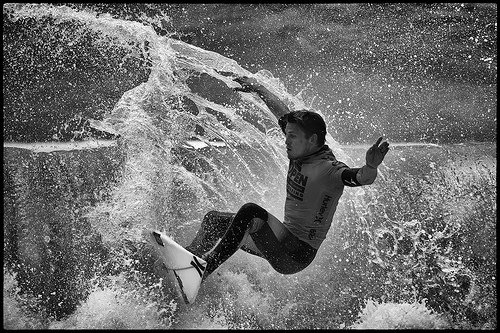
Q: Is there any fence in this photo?
A: No, there are no fences.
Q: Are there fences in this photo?
A: No, there are no fences.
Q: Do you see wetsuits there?
A: Yes, there is a wetsuit.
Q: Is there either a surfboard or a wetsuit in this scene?
A: Yes, there is a wetsuit.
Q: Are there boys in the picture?
A: No, there are no boys.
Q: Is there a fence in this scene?
A: No, there are no fences.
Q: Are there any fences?
A: No, there are no fences.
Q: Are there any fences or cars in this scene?
A: No, there are no fences or cars.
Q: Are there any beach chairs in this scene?
A: No, there are no beach chairs.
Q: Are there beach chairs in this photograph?
A: No, there are no beach chairs.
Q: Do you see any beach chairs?
A: No, there are no beach chairs.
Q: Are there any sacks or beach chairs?
A: No, there are no beach chairs or sacks.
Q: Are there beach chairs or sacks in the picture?
A: No, there are no beach chairs or sacks.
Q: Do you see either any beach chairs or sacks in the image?
A: No, there are no beach chairs or sacks.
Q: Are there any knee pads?
A: No, there are no knee pads.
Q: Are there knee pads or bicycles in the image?
A: No, there are no knee pads or bicycles.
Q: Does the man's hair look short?
A: Yes, the hair is short.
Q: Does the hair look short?
A: Yes, the hair is short.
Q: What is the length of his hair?
A: The hair is short.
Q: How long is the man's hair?
A: The hair is short.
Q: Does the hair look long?
A: No, the hair is short.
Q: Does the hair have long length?
A: No, the hair is short.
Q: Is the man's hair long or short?
A: The hair is short.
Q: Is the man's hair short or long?
A: The hair is short.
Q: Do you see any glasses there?
A: No, there are no glasses.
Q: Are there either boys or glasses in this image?
A: No, there are no glasses or boys.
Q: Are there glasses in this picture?
A: No, there are no glasses.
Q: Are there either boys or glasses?
A: No, there are no glasses or boys.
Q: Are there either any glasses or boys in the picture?
A: No, there are no glasses or boys.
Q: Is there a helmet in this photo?
A: No, there are no helmets.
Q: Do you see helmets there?
A: No, there are no helmets.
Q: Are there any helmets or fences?
A: No, there are no helmets or fences.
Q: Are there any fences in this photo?
A: No, there are no fences.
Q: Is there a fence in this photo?
A: No, there are no fences.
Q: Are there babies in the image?
A: No, there are no babies.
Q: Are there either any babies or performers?
A: No, there are no babies or performers.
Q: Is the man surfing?
A: Yes, the man is surfing.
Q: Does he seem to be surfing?
A: Yes, the man is surfing.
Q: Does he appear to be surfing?
A: Yes, the man is surfing.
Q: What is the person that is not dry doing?
A: The man is surfing.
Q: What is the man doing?
A: The man is surfing.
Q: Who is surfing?
A: The man is surfing.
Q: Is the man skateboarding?
A: No, the man is surfing.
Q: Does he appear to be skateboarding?
A: No, the man is surfing.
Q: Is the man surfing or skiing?
A: The man is surfing.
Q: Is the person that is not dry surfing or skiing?
A: The man is surfing.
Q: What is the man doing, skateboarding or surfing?
A: The man is surfing.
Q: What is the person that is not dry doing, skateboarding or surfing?
A: The man is surfing.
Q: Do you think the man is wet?
A: Yes, the man is wet.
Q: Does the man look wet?
A: Yes, the man is wet.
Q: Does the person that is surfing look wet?
A: Yes, the man is wet.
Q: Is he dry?
A: No, the man is wet.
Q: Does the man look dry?
A: No, the man is wet.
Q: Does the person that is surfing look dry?
A: No, the man is wet.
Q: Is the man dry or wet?
A: The man is wet.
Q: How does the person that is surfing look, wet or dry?
A: The man is wet.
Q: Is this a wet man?
A: Yes, this is a wet man.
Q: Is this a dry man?
A: No, this is a wet man.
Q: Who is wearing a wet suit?
A: The man is wearing a wet suit.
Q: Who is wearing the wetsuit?
A: The man is wearing a wet suit.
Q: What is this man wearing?
A: The man is wearing a wetsuit.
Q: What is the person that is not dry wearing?
A: The man is wearing a wetsuit.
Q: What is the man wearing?
A: The man is wearing a wetsuit.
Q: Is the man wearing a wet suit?
A: Yes, the man is wearing a wet suit.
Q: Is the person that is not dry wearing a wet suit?
A: Yes, the man is wearing a wet suit.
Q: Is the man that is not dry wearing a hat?
A: No, the man is wearing a wet suit.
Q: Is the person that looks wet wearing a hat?
A: No, the man is wearing a wet suit.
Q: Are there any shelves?
A: No, there are no shelves.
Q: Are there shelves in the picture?
A: No, there are no shelves.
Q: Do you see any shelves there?
A: No, there are no shelves.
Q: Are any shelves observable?
A: No, there are no shelves.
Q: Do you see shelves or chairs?
A: No, there are no shelves or chairs.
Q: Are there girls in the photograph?
A: No, there are no girls.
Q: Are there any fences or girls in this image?
A: No, there are no girls or fences.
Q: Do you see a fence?
A: No, there are no fences.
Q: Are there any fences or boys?
A: No, there are no fences or boys.